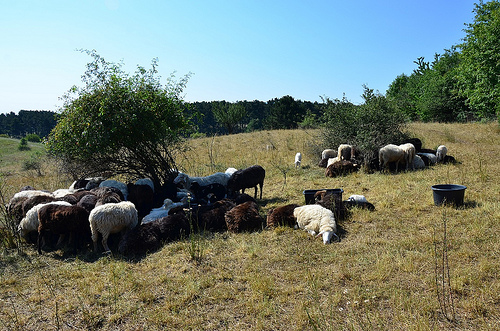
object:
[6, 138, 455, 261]
herd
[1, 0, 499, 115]
clouds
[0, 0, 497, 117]
sky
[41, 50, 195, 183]
tree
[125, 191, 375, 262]
sleeping sheep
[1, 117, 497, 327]
grass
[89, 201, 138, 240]
wool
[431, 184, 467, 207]
black bucket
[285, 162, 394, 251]
ground